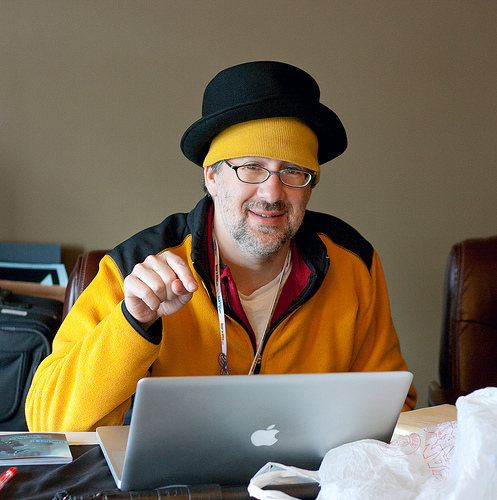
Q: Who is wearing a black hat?
A: The man with the laptop.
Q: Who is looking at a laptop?
A: The man with the black hat.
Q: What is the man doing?
A: Pointing at the computer.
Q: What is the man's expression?
A: Smiling.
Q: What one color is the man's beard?
A: Grey.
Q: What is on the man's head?
A: A hat.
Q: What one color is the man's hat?
A: Black.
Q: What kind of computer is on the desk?
A: A laptop.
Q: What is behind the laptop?
A: A plastic bag.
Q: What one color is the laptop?
A: Silver.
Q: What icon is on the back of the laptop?
A: An apple.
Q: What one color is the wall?
A: Tan.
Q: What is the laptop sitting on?
A: A desk.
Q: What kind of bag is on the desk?
A: Plastic bag.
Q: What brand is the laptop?
A: Apple.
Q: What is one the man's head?
A: Hat.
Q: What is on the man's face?
A: Glasses.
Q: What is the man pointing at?
A: The screen.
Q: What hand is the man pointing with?
A: Right.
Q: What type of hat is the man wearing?
A: Knit.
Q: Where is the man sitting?
A: The chair.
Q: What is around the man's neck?
A: A lanyard.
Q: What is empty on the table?
A: Shopping bag.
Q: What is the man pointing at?
A: The laptop.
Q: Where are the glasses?
A: On the man's face.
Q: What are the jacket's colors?
A: Yellow and black.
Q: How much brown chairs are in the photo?
A: Two.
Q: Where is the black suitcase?
A: Behind the man.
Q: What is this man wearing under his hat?
A: A cap.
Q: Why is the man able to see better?
A: He is wearing glasses.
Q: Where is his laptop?
A: On the desk.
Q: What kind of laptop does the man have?
A: Apple.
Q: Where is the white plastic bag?
A: On the desk.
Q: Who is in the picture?
A: A man.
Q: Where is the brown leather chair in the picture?
A: To the far right of the picture.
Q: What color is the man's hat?
A: Black.